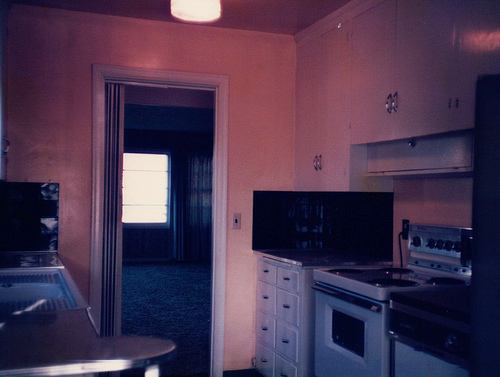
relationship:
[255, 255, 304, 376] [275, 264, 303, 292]
drawers are closed drawer closed drawer is closed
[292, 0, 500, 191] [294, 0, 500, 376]
cabinets are above stove below cabinets above stove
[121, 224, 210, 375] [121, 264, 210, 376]
carpet is to wall wall by carpet carpet wall to wall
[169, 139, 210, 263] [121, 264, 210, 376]
carpet is on window carpet hanging floor has carpet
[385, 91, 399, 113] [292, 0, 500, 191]
pulls are chrome pulls are for door cupboards are white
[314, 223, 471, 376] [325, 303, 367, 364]
oven was window window on door window on oven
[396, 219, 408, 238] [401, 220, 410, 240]
kitchen has plug kitchen has wall plug is on wall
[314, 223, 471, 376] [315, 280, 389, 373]
stove has handle stove has door door on stove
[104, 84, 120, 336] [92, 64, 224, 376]
door is folding door in doorway doorway has door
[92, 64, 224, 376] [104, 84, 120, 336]
door has divider room living divider in door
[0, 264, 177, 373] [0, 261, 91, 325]
countertop is metal kitchen has sink single basin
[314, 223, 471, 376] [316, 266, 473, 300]
kitchen has oven oven electric kitchen has stove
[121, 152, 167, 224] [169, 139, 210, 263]
room has windows room has curtain curtain on window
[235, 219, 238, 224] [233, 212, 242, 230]
switch is black plate white switch on wall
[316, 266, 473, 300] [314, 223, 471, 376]
kitchen has stove stove in kitchen kitchen stove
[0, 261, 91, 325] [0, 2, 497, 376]
single basin sink in kitchen sink is kitchen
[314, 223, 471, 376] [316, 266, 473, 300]
stove has top top on stove stove top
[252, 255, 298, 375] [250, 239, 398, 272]
drawers beneath counter top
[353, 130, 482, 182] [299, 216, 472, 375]
exhaust fan installed over stove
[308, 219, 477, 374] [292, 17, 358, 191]
stove under cabinets are above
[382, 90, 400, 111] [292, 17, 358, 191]
handles on cabinets are above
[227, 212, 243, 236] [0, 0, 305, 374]
switch on wall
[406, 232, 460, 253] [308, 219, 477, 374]
knobs on front stove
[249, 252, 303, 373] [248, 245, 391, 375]
drawers on cabinet